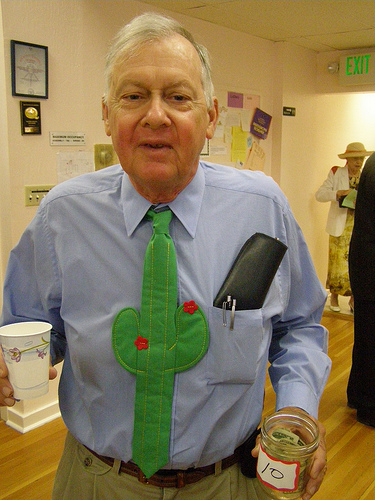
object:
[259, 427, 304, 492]
money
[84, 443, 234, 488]
belt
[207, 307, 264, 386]
pocket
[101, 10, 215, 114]
hair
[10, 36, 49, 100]
plaque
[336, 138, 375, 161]
hat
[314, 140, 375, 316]
woman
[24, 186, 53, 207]
panel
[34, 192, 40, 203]
buttons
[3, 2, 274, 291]
wall